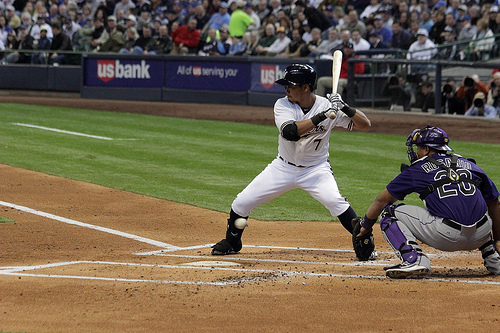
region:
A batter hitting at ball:
[224, 39, 374, 257]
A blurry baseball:
[221, 211, 268, 249]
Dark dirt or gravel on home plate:
[153, 234, 340, 296]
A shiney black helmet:
[269, 60, 330, 92]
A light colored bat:
[331, 45, 346, 113]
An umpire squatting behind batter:
[386, 125, 478, 260]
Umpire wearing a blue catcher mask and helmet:
[396, 124, 456, 151]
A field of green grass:
[126, 112, 250, 179]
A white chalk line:
[13, 187, 183, 266]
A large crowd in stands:
[80, 9, 208, 45]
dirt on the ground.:
[310, 300, 357, 321]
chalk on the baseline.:
[93, 210, 125, 240]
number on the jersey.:
[308, 138, 325, 157]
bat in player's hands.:
[325, 43, 345, 90]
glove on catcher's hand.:
[347, 213, 374, 270]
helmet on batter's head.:
[266, 54, 318, 90]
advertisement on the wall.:
[85, 60, 156, 81]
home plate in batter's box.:
[187, 254, 240, 274]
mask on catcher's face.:
[398, 125, 418, 160]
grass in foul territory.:
[195, 138, 233, 154]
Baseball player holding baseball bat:
[206, 48, 371, 266]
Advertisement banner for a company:
[81, 55, 253, 95]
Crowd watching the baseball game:
[0, 0, 498, 115]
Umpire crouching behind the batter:
[349, 123, 498, 285]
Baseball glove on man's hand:
[349, 218, 376, 267]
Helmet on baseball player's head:
[275, 60, 322, 100]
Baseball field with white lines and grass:
[0, 94, 497, 331]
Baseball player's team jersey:
[271, 95, 355, 170]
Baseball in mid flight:
[233, 210, 249, 232]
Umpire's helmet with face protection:
[400, 125, 461, 164]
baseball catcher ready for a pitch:
[348, 125, 498, 281]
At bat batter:
[205, 60, 370, 258]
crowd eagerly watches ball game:
[0, 1, 498, 61]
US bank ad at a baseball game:
[82, 54, 277, 90]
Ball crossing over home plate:
[2, 197, 494, 317]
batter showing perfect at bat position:
[207, 48, 373, 256]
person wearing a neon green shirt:
[222, 5, 255, 45]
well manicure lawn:
[3, 121, 270, 166]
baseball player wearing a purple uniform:
[351, 127, 497, 277]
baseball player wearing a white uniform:
[210, 50, 375, 255]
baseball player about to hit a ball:
[214, 45, 376, 260]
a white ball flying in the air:
[234, 216, 248, 229]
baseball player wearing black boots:
[216, 209, 371, 262]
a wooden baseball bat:
[330, 49, 344, 121]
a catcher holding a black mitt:
[350, 219, 377, 259]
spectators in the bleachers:
[5, 0, 497, 115]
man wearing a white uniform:
[226, 95, 352, 216]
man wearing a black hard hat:
[277, 65, 317, 90]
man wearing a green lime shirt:
[227, 10, 253, 37]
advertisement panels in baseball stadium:
[81, 56, 309, 93]